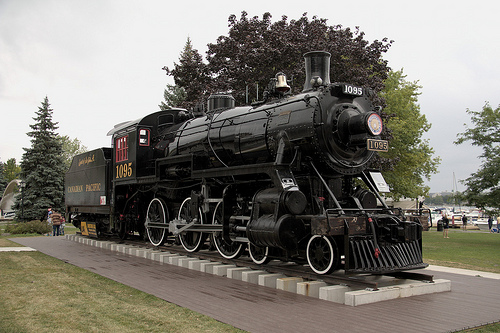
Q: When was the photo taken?
A: Daytime.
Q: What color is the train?
A: Black.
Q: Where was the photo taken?
A: At a park.